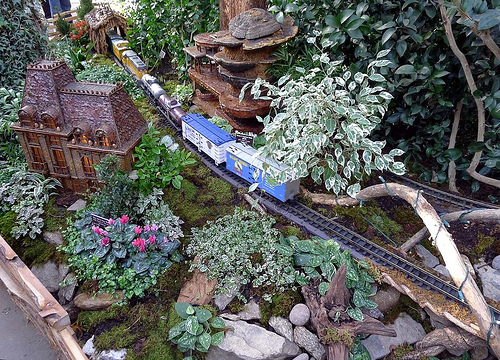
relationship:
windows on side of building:
[22, 109, 119, 179] [8, 55, 150, 192]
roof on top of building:
[19, 57, 150, 140] [8, 55, 150, 192]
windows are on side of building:
[22, 109, 119, 179] [8, 55, 150, 192]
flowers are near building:
[88, 215, 175, 265] [8, 55, 150, 192]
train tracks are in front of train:
[103, 34, 479, 309] [110, 32, 306, 205]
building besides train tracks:
[8, 55, 150, 192] [103, 34, 479, 309]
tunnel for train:
[83, 5, 136, 54] [110, 32, 306, 205]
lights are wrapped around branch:
[328, 174, 496, 341] [296, 177, 500, 354]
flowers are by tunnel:
[68, 19, 87, 42] [83, 5, 136, 54]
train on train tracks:
[110, 32, 306, 205] [103, 34, 479, 309]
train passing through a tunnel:
[110, 32, 306, 205] [83, 5, 136, 54]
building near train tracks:
[8, 55, 150, 192] [103, 34, 479, 309]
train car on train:
[224, 141, 305, 202] [110, 32, 306, 205]